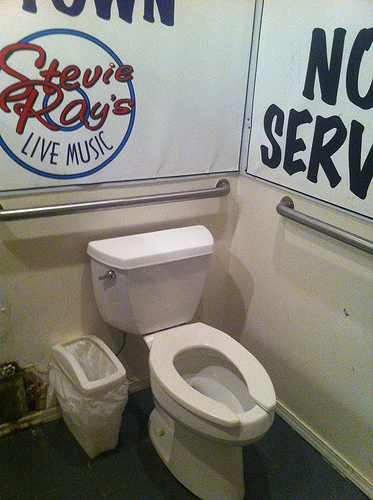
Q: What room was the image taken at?
A: It was taken at the bathroom.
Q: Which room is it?
A: It is a bathroom.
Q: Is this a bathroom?
A: Yes, it is a bathroom.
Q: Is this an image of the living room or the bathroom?
A: It is showing the bathroom.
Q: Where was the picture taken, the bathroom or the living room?
A: It was taken at the bathroom.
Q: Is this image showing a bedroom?
A: No, the picture is showing a bathroom.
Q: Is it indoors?
A: Yes, it is indoors.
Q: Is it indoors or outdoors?
A: It is indoors.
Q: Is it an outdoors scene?
A: No, it is indoors.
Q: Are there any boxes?
A: No, there are no boxes.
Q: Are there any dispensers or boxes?
A: No, there are no boxes or dispensers.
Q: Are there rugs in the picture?
A: No, there are no rugs.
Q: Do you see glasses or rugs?
A: No, there are no rugs or glasses.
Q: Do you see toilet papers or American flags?
A: No, there are no toilet papers or American flags.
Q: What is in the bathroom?
A: The toilet is in the bathroom.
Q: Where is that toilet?
A: The toilet is in the bathroom.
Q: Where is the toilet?
A: The toilet is in the bathroom.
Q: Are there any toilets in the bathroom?
A: Yes, there is a toilet in the bathroom.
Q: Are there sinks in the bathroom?
A: No, there is a toilet in the bathroom.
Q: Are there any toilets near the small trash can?
A: Yes, there is a toilet near the garbage bin.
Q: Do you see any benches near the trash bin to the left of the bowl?
A: No, there is a toilet near the trash can.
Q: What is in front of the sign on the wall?
A: The toilet is in front of the sign.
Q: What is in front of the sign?
A: The toilet is in front of the sign.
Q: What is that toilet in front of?
A: The toilet is in front of the sign.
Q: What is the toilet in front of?
A: The toilet is in front of the sign.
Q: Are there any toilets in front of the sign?
A: Yes, there is a toilet in front of the sign.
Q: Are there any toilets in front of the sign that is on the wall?
A: Yes, there is a toilet in front of the sign.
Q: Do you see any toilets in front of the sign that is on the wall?
A: Yes, there is a toilet in front of the sign.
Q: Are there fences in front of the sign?
A: No, there is a toilet in front of the sign.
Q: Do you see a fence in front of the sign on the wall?
A: No, there is a toilet in front of the sign.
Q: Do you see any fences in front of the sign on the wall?
A: No, there is a toilet in front of the sign.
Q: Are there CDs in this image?
A: No, there are no cds.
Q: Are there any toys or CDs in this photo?
A: No, there are no CDs or toys.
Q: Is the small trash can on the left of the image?
A: Yes, the trashcan is on the left of the image.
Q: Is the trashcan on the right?
A: No, the trashcan is on the left of the image.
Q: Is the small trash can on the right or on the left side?
A: The garbage can is on the left of the image.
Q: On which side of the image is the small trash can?
A: The garbage bin is on the left of the image.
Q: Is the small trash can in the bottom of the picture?
A: Yes, the garbage bin is in the bottom of the image.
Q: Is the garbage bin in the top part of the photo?
A: No, the garbage bin is in the bottom of the image.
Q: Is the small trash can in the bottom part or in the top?
A: The garbage can is in the bottom of the image.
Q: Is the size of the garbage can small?
A: Yes, the garbage can is small.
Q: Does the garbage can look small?
A: Yes, the garbage can is small.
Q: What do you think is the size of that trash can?
A: The trash can is small.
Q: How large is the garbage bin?
A: The garbage bin is small.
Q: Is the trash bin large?
A: No, the trash bin is small.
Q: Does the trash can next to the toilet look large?
A: No, the garbage bin is small.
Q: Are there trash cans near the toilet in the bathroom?
A: Yes, there is a trash can near the toilet.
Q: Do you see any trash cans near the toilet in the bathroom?
A: Yes, there is a trash can near the toilet.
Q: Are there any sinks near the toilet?
A: No, there is a trash can near the toilet.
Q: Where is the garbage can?
A: The garbage can is on the floor.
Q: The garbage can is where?
A: The garbage can is on the floor.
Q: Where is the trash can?
A: The garbage can is on the floor.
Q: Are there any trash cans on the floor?
A: Yes, there is a trash can on the floor.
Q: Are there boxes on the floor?
A: No, there is a trash can on the floor.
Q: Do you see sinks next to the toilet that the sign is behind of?
A: No, there is a trash can next to the toilet.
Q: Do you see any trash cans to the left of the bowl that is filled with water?
A: Yes, there is a trash can to the left of the bowl.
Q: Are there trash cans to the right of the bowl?
A: No, the trash can is to the left of the bowl.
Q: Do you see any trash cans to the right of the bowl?
A: No, the trash can is to the left of the bowl.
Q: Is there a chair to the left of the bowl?
A: No, there is a trash can to the left of the bowl.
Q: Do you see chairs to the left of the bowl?
A: No, there is a trash can to the left of the bowl.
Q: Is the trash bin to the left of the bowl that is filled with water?
A: Yes, the trash bin is to the left of the bowl.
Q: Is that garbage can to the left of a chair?
A: No, the garbage can is to the left of the bowl.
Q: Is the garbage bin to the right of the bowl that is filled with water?
A: No, the garbage bin is to the left of the bowl.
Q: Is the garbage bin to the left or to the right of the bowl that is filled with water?
A: The garbage bin is to the left of the bowl.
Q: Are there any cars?
A: No, there are no cars.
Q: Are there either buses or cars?
A: No, there are no cars or buses.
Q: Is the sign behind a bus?
A: No, the sign is behind the toilet.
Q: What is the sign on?
A: The sign is on the wall.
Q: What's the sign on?
A: The sign is on the wall.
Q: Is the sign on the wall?
A: Yes, the sign is on the wall.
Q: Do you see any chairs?
A: No, there are no chairs.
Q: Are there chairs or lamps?
A: No, there are no chairs or lamps.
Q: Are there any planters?
A: No, there are no planters.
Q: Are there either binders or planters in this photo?
A: No, there are no planters or binders.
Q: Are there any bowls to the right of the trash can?
A: Yes, there is a bowl to the right of the trash can.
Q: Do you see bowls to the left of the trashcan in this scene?
A: No, the bowl is to the right of the trashcan.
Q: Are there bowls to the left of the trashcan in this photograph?
A: No, the bowl is to the right of the trashcan.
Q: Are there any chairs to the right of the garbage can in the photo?
A: No, there is a bowl to the right of the garbage can.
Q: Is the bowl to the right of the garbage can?
A: Yes, the bowl is to the right of the garbage can.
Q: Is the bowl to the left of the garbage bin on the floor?
A: No, the bowl is to the right of the garbage can.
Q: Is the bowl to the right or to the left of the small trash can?
A: The bowl is to the right of the trash bin.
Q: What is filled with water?
A: The bowl is filled with water.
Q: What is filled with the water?
A: The bowl is filled with water.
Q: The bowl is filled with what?
A: The bowl is filled with water.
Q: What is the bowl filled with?
A: The bowl is filled with water.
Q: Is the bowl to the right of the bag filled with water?
A: Yes, the bowl is filled with water.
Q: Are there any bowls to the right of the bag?
A: Yes, there is a bowl to the right of the bag.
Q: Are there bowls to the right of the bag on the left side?
A: Yes, there is a bowl to the right of the bag.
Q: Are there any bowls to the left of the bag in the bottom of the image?
A: No, the bowl is to the right of the bag.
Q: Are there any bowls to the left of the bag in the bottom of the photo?
A: No, the bowl is to the right of the bag.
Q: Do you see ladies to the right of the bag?
A: No, there is a bowl to the right of the bag.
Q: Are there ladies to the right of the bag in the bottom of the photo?
A: No, there is a bowl to the right of the bag.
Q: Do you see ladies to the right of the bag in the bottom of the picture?
A: No, there is a bowl to the right of the bag.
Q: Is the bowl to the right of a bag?
A: Yes, the bowl is to the right of a bag.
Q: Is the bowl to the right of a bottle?
A: No, the bowl is to the right of a bag.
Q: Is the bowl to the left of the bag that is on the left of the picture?
A: No, the bowl is to the right of the bag.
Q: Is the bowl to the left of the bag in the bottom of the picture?
A: No, the bowl is to the right of the bag.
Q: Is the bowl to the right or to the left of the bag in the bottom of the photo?
A: The bowl is to the right of the bag.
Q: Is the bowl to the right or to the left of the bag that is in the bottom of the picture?
A: The bowl is to the right of the bag.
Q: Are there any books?
A: No, there are no books.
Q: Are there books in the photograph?
A: No, there are no books.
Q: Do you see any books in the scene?
A: No, there are no books.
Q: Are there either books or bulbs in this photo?
A: No, there are no books or bulbs.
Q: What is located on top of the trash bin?
A: The lid is on top of the trash bin.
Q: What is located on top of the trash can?
A: The lid is on top of the trash bin.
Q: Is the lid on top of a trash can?
A: Yes, the lid is on top of a trash can.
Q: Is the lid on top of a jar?
A: No, the lid is on top of a trash can.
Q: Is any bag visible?
A: Yes, there is a bag.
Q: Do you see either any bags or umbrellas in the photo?
A: Yes, there is a bag.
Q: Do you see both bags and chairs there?
A: No, there is a bag but no chairs.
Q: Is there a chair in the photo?
A: No, there are no chairs.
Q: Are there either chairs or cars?
A: No, there are no chairs or cars.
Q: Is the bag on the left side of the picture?
A: Yes, the bag is on the left of the image.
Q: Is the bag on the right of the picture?
A: No, the bag is on the left of the image.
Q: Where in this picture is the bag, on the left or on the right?
A: The bag is on the left of the image.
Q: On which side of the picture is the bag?
A: The bag is on the left of the image.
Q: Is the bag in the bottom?
A: Yes, the bag is in the bottom of the image.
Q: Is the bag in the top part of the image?
A: No, the bag is in the bottom of the image.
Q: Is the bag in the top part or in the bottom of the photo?
A: The bag is in the bottom of the image.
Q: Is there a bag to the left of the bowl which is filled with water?
A: Yes, there is a bag to the left of the bowl.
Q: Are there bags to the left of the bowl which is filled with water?
A: Yes, there is a bag to the left of the bowl.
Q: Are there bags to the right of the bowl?
A: No, the bag is to the left of the bowl.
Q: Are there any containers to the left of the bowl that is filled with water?
A: No, there is a bag to the left of the bowl.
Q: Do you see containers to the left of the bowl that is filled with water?
A: No, there is a bag to the left of the bowl.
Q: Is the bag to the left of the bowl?
A: Yes, the bag is to the left of the bowl.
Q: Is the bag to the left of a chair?
A: No, the bag is to the left of the bowl.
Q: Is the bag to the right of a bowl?
A: No, the bag is to the left of a bowl.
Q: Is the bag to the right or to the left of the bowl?
A: The bag is to the left of the bowl.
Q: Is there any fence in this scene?
A: No, there are no fences.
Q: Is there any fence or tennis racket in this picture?
A: No, there are no fences or rackets.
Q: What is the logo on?
A: The logo is on the wall.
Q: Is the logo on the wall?
A: Yes, the logo is on the wall.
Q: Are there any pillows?
A: No, there are no pillows.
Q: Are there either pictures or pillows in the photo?
A: No, there are no pillows or pictures.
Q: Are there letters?
A: Yes, there are letters.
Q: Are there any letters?
A: Yes, there are letters.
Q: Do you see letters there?
A: Yes, there are letters.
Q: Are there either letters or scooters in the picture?
A: Yes, there are letters.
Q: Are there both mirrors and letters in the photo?
A: No, there are letters but no mirrors.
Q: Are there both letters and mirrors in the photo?
A: No, there are letters but no mirrors.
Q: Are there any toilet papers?
A: No, there are no toilet papers.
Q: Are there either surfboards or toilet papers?
A: No, there are no toilet papers or surfboards.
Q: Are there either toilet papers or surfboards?
A: No, there are no toilet papers or surfboards.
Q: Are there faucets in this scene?
A: No, there are no faucets.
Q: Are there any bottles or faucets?
A: No, there are no faucets or bottles.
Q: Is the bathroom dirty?
A: Yes, the bathroom is dirty.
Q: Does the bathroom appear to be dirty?
A: Yes, the bathroom is dirty.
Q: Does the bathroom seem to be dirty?
A: Yes, the bathroom is dirty.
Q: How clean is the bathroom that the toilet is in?
A: The bathroom is dirty.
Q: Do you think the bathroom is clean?
A: No, the bathroom is dirty.